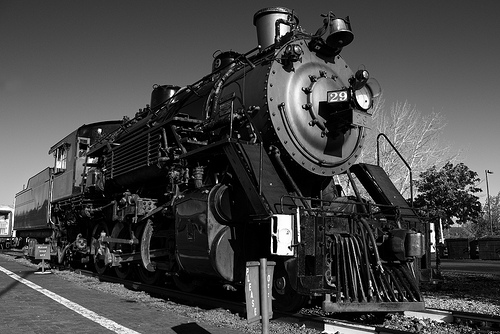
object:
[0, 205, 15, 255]
cars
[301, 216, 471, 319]
cow catcher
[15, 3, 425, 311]
train engine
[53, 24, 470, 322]
engineer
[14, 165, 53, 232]
caboose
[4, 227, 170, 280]
wheels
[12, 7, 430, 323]
train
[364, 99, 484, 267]
trees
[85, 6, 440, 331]
locomotive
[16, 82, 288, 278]
side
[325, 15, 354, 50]
bell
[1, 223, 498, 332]
railroad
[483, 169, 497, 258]
lamp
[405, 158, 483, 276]
tree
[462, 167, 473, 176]
leaf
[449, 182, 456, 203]
leaf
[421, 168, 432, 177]
leaf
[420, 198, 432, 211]
leaf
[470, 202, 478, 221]
leaf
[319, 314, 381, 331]
gravel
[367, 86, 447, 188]
tree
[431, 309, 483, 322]
gravel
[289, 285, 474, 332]
tracks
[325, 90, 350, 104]
29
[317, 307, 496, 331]
rail